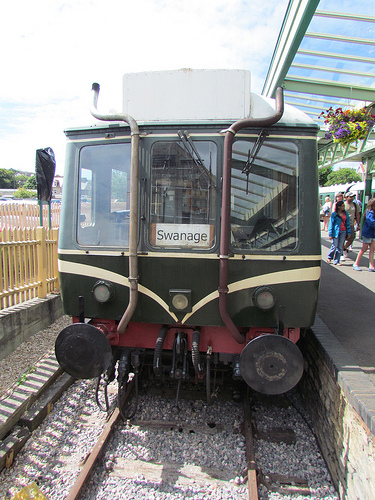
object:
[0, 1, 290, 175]
cloud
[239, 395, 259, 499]
track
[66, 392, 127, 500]
tracks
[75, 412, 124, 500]
side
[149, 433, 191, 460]
gravel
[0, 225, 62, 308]
fence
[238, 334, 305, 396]
stopper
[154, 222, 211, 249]
sign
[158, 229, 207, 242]
swanage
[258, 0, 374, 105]
awning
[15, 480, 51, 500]
zander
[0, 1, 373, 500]
photo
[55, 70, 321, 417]
train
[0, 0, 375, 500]
station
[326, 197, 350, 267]
passenger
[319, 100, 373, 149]
flowers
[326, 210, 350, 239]
jacket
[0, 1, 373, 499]
day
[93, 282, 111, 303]
lights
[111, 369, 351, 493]
shadow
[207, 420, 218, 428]
wood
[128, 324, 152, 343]
color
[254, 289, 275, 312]
light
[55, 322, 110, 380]
disc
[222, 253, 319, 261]
line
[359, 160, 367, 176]
pipe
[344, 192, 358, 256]
person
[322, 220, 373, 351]
platform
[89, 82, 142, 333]
pipe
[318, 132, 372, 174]
structure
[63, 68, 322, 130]
top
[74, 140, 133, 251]
window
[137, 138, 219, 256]
window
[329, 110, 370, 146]
basket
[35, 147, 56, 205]
bag